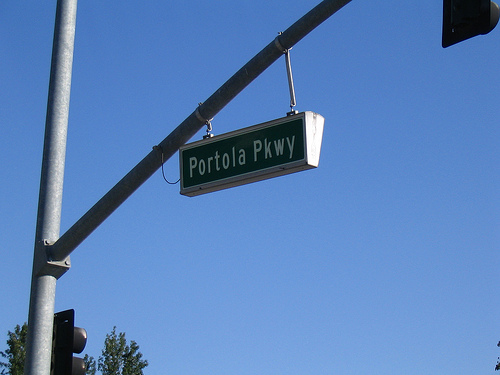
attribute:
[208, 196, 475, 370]
sky — blue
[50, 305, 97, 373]
light — silver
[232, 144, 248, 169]
letter — white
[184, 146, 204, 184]
letter — white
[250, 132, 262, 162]
letter — white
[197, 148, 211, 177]
letter — white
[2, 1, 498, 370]
sky — blue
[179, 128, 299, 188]
words — white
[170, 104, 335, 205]
sign — green, white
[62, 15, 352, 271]
pole — horizontal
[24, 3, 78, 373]
pole — metal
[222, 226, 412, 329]
sky — clear, blue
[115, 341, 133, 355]
leaves — green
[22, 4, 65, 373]
pole — metal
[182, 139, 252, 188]
portolo — word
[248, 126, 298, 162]
pkwy — word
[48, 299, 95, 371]
street light — black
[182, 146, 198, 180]
p — white